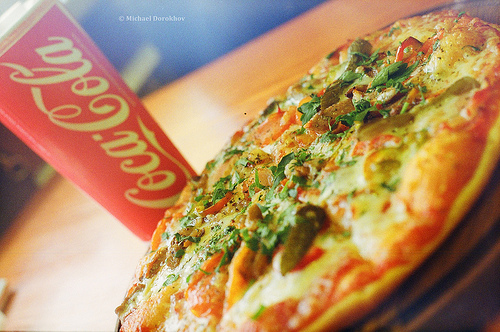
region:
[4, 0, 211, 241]
this is a glass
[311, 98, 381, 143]
this is a vegetable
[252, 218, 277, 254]
this is a vegetable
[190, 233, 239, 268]
this is a vegetable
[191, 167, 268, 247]
this is a vegetable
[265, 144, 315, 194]
this is a vegetable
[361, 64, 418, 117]
this is a vegetable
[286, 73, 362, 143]
this is a vegetable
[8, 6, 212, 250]
Coca-cola cup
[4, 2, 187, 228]
Coca-cola cup on a table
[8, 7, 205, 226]
Coca-cola cup on a wooden table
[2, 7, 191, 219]
Coca-cola cup sideways view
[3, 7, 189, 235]
Red cup with white coca-cola writing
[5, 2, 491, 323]
Coca-cola cup next to an individual pizza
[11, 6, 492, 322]
Coca-cola cup next to an individual pizza on a table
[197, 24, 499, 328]
Part of a pizza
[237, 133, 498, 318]
Pizza toppings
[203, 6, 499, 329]
Part of a pizza on a wooden table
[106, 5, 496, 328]
A pizza in the foreground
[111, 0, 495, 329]
The pizza is fully cooked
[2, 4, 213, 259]
A plastic cup in the foreground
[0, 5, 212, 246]
A red plastic cup in the foreground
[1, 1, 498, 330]
Pizza is on the table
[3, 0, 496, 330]
The table is made of wood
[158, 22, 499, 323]
Pizza has green colored toppings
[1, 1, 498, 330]
Photo was taken in the daytime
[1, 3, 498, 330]
Photo was taken indoors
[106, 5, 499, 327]
The pizza crust is thin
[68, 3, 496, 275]
a smal pizza on a table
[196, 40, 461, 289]
a small pizza on a plate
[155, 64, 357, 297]
a cooked small pizza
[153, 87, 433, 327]
a small cooked pizza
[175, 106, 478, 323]
a small baked pizza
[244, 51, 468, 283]
a person size pizza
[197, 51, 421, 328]
a pizza cut into slices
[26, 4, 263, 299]
a drink on teh table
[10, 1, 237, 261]
a cocacola drink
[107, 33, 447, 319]
a tabel with a pizza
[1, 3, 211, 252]
a red and white drinking cup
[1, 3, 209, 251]
cardboard drinking cup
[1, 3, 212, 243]
cup advertises coca cola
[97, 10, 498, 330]
a circular cooked pizza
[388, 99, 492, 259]
tomato and cheese on the edge of a pizza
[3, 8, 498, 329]
pizza and a drink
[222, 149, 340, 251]
green herbs on a pizza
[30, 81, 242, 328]
light reflected on a wooden table surface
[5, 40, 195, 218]
the words coca cola on the side of a cup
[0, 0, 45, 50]
rim of a paper cup